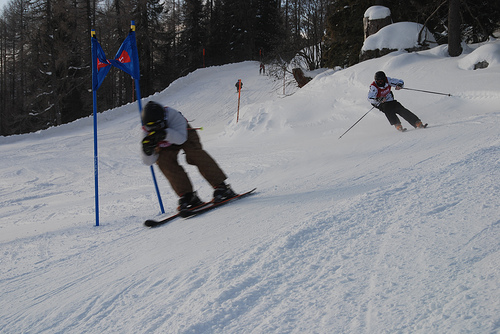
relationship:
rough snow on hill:
[0, 5, 500, 334] [1, 38, 498, 332]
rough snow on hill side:
[0, 5, 500, 334] [2, 126, 497, 330]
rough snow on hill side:
[0, 5, 500, 334] [0, 45, 484, 329]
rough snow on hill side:
[0, 5, 500, 334] [279, 190, 361, 257]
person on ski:
[366, 70, 421, 131] [395, 127, 407, 134]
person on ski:
[141, 98, 232, 215] [143, 202, 191, 229]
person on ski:
[141, 98, 232, 215] [181, 186, 256, 216]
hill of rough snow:
[227, 35, 494, 146] [0, 5, 500, 334]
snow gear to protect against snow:
[140, 124, 170, 153] [171, 219, 233, 248]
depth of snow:
[353, 7, 444, 60] [359, 48, 441, 72]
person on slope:
[139, 100, 236, 211] [0, 70, 500, 332]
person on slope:
[367, 71, 423, 130] [0, 70, 500, 332]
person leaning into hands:
[139, 100, 236, 211] [132, 127, 177, 155]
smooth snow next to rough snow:
[234, 68, 490, 163] [207, 142, 498, 332]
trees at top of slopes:
[2, 0, 485, 137] [5, 38, 498, 135]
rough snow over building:
[0, 5, 500, 334] [360, 5, 438, 60]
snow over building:
[362, 21, 437, 51] [360, 5, 438, 60]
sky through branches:
[0, 0, 325, 60] [1, 7, 283, 132]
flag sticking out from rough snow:
[91, 20, 165, 226] [0, 5, 500, 334]